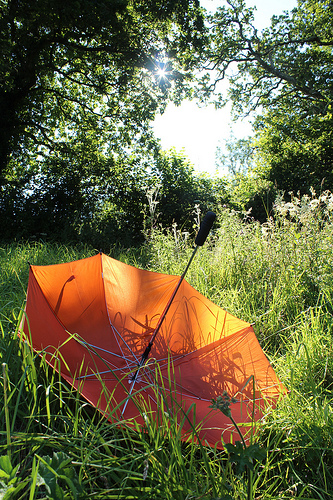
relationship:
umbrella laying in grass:
[22, 211, 287, 456] [0, 236, 331, 499]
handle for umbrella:
[128, 211, 217, 384] [22, 211, 287, 456]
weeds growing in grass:
[262, 189, 332, 242] [0, 236, 331, 499]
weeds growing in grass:
[168, 203, 201, 249] [0, 236, 331, 499]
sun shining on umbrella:
[156, 68, 169, 81] [22, 211, 287, 456]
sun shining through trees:
[156, 68, 169, 81] [2, 0, 212, 244]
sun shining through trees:
[156, 68, 169, 81] [201, 0, 332, 199]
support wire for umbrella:
[111, 324, 141, 368] [22, 211, 287, 456]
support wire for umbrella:
[136, 352, 185, 379] [22, 211, 287, 456]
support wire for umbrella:
[134, 366, 200, 401] [22, 211, 287, 456]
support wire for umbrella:
[121, 367, 141, 417] [22, 211, 287, 456]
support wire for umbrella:
[78, 364, 138, 380] [22, 211, 287, 456]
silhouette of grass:
[112, 297, 262, 399] [0, 236, 331, 499]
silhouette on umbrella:
[112, 297, 262, 399] [22, 211, 287, 456]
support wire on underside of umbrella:
[111, 324, 141, 368] [22, 211, 287, 456]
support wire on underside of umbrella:
[136, 352, 185, 379] [22, 211, 287, 456]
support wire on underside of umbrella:
[134, 366, 200, 401] [22, 211, 287, 456]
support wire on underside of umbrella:
[121, 367, 141, 417] [22, 211, 287, 456]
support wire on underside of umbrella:
[78, 364, 138, 380] [22, 211, 287, 456]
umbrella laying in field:
[22, 211, 287, 456] [0, 235, 331, 498]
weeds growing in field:
[262, 189, 332, 242] [0, 235, 331, 498]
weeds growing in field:
[168, 203, 201, 249] [0, 235, 331, 498]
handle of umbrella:
[128, 211, 217, 384] [22, 211, 287, 456]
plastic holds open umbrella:
[142, 342, 152, 361] [22, 211, 287, 456]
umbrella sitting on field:
[22, 211, 287, 456] [0, 240, 331, 497]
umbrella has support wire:
[22, 211, 287, 456] [111, 324, 141, 368]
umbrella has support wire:
[22, 211, 287, 456] [136, 352, 185, 379]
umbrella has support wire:
[22, 211, 287, 456] [134, 366, 200, 401]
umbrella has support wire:
[22, 211, 287, 456] [121, 367, 141, 417]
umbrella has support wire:
[22, 211, 287, 456] [78, 364, 138, 380]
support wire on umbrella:
[111, 324, 141, 368] [22, 211, 287, 456]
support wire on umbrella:
[136, 352, 185, 379] [22, 211, 287, 456]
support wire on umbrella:
[134, 366, 200, 401] [22, 211, 287, 456]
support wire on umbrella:
[121, 367, 141, 417] [22, 211, 287, 456]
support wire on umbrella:
[78, 364, 138, 380] [22, 211, 287, 456]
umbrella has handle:
[22, 211, 287, 456] [128, 211, 217, 384]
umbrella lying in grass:
[22, 211, 287, 456] [0, 236, 331, 499]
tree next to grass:
[23, 173, 89, 245] [0, 236, 331, 499]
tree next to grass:
[89, 185, 150, 250] [0, 236, 331, 499]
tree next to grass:
[155, 151, 220, 245] [0, 236, 331, 499]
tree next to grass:
[234, 179, 276, 222] [0, 236, 331, 499]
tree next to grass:
[259, 133, 331, 194] [0, 236, 331, 499]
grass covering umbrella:
[0, 236, 331, 499] [22, 211, 287, 456]